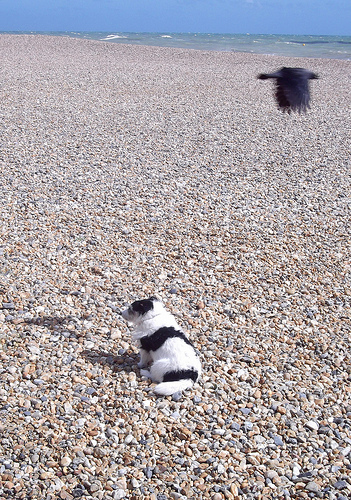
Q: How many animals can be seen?
A: Two.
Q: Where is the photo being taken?
A: The beach.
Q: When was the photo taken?
A: Day time.